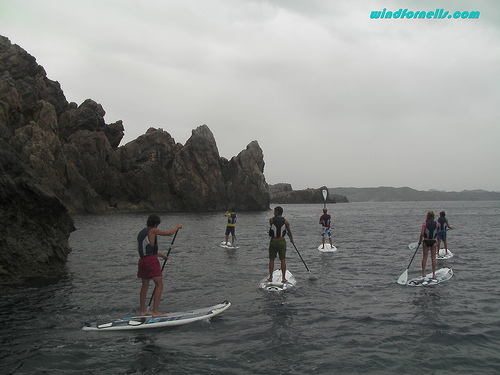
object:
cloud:
[52, 7, 152, 142]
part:
[242, 16, 337, 112]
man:
[224, 210, 237, 246]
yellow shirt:
[227, 213, 238, 227]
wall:
[363, 187, 396, 200]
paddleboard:
[258, 268, 297, 292]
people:
[437, 211, 453, 255]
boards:
[258, 268, 296, 292]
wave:
[212, 287, 497, 373]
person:
[417, 211, 439, 278]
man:
[318, 208, 333, 249]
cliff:
[1, 48, 222, 212]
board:
[81, 300, 231, 331]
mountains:
[347, 180, 479, 201]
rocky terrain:
[8, 45, 279, 220]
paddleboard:
[214, 239, 237, 249]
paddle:
[320, 186, 329, 210]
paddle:
[146, 226, 181, 312]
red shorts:
[137, 255, 162, 280]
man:
[136, 214, 181, 317]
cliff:
[231, 137, 268, 196]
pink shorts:
[137, 255, 163, 278]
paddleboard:
[316, 243, 335, 252]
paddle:
[397, 244, 421, 285]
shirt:
[423, 222, 439, 239]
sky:
[1, 0, 484, 190]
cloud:
[157, 8, 326, 98]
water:
[353, 320, 410, 358]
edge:
[102, 313, 217, 330]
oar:
[289, 237, 318, 280]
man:
[267, 206, 289, 282]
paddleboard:
[434, 245, 452, 260]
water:
[478, 290, 499, 374]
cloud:
[405, 3, 496, 83]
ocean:
[10, 183, 499, 373]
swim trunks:
[268, 239, 286, 260]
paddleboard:
[406, 267, 454, 287]